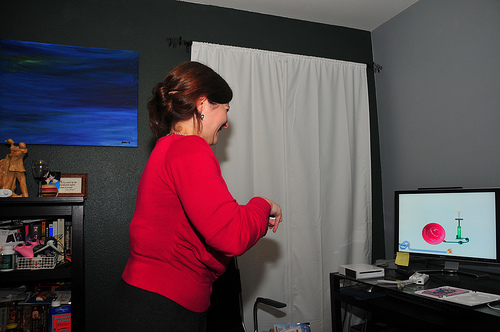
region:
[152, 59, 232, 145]
The lady has red hair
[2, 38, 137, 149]
The painting is blue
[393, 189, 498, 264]
The computer monitor is on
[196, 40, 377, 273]
The curtain is white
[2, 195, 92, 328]
The bookshelf is wooden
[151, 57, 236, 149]
The lady is smiling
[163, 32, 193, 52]
The curtain rod is black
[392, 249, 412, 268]
The post it note is on the monitor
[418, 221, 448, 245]
A pink ball on the screen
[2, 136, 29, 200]
Figurine on the bookshelf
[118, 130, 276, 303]
THE WOMAN'S SHIRT HAS LONG SLEEVES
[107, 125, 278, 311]
THE WOMAN IS WEARING A RED SHIRT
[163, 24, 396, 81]
THE CURTAIN ROD IS BLACK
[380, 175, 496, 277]
THIS IS A MONITOR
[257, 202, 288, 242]
THE WOMAN IS HOLDING A CONTROLLER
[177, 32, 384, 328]
THE CURTAIN IS WHITE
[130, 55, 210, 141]
THE WOMAN HAS HER HAIR IN AN UPDO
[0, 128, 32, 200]
THE STATUE IS ON THE SHELF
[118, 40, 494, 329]
woman looking at television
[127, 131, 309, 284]
woman wearing a red shirt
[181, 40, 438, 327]
long white window curtain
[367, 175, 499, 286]
small black flat screen television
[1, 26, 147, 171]
painting on the wall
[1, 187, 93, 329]
shelf filled with items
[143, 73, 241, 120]
red hair on woman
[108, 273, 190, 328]
woman wearing dark bottoms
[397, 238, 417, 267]
post it on television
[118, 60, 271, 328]
Woman in a pink shirt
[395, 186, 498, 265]
A computer monitor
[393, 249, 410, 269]
A yellow sticky note on a computer monitor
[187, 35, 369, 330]
Drape hanging from the wall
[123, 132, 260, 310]
Pink shirt on a woman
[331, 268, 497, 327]
A black computer desk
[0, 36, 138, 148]
Blue picture on a gray wall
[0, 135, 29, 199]
Statue on a book case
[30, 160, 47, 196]
A wine glass on a book case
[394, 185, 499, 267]
a black monitor on a desk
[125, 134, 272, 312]
woman wearing a pink sweater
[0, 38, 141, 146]
a blue painting on a wall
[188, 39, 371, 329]
white curtains on a window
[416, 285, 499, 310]
an opened book on a desk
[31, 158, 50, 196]
a glass of wine on top of a bookshelf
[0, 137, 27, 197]
a wood sculpture on top of a bookshelf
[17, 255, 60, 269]
a white plastic box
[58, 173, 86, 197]
a wooden frame